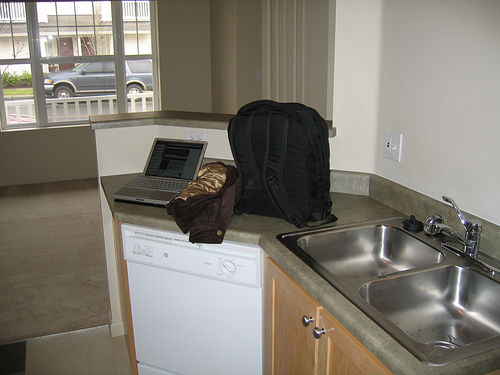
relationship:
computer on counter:
[112, 137, 208, 208] [97, 151, 414, 253]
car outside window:
[42, 56, 156, 101] [0, 5, 152, 122]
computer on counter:
[112, 137, 208, 208] [247, 216, 277, 230]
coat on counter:
[167, 161, 239, 244] [235, 208, 278, 242]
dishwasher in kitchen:
[113, 244, 250, 353] [90, 0, 500, 370]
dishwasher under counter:
[120, 222, 265, 375] [104, 168, 360, 232]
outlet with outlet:
[376, 123, 410, 165] [383, 130, 403, 163]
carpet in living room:
[1, 186, 106, 320] [1, 0, 141, 320]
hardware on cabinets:
[300, 316, 323, 341] [265, 256, 404, 372]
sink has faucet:
[279, 199, 499, 357] [428, 213, 478, 259]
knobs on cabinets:
[298, 310, 332, 339] [263, 254, 396, 374]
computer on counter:
[112, 137, 208, 208] [108, 170, 373, 240]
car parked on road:
[41, 56, 157, 99] [7, 94, 160, 114]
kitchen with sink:
[90, 5, 498, 370] [275, 216, 495, 364]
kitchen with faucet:
[90, 5, 498, 370] [422, 189, 493, 282]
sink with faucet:
[275, 216, 495, 364] [422, 189, 493, 282]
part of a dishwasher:
[172, 279, 198, 339] [120, 222, 265, 375]